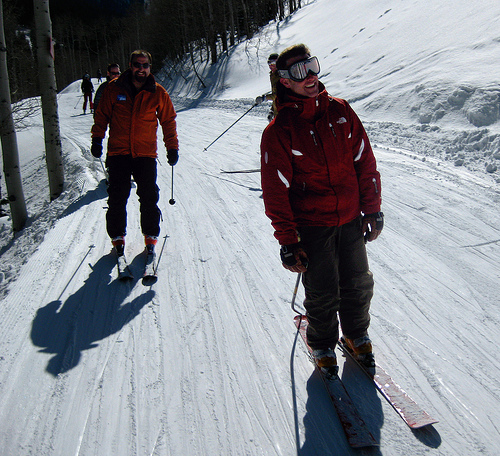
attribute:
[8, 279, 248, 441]
snow — white 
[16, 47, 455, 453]
snow — white 